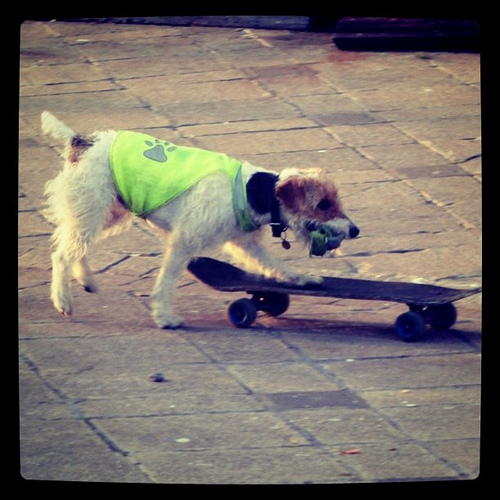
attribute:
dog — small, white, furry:
[28, 92, 368, 368]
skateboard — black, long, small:
[178, 249, 475, 339]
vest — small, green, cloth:
[99, 127, 241, 219]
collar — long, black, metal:
[256, 173, 290, 237]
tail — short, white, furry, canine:
[39, 108, 79, 148]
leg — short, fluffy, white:
[53, 164, 93, 323]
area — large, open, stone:
[27, 23, 474, 477]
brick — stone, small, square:
[67, 340, 418, 468]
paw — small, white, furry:
[152, 301, 189, 328]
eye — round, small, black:
[315, 197, 339, 216]